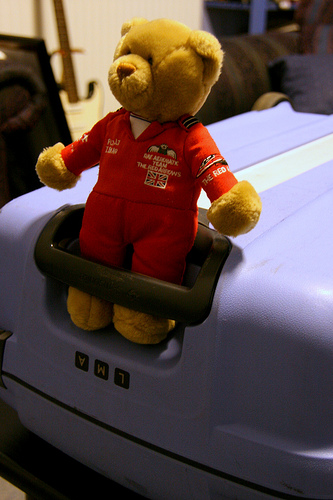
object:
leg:
[66, 200, 125, 331]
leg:
[113, 211, 198, 344]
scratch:
[251, 257, 279, 276]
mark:
[273, 477, 303, 491]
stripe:
[228, 135, 332, 195]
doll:
[35, 16, 263, 344]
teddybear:
[111, 31, 223, 200]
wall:
[33, 3, 189, 101]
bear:
[35, 16, 261, 344]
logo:
[144, 169, 169, 190]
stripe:
[0, 369, 304, 499]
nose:
[116, 61, 135, 80]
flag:
[143, 167, 168, 187]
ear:
[188, 30, 223, 86]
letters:
[76, 348, 92, 372]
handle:
[34, 206, 233, 326]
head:
[106, 16, 224, 126]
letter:
[93, 358, 109, 381]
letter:
[111, 367, 129, 386]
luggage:
[0, 92, 332, 496]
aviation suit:
[60, 108, 238, 285]